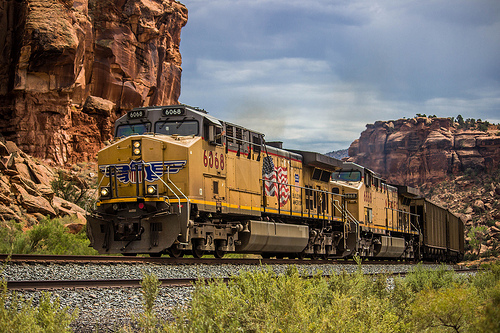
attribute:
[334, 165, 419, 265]
train car — yellow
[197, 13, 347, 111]
clouds — white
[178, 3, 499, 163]
sky — blue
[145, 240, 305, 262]
wheels — small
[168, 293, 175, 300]
rocks — little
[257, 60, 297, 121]
clouds — white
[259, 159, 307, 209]
flag — American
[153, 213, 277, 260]
wheels — steel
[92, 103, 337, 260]
train car — yellow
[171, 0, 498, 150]
sky — blue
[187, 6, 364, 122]
clouds — white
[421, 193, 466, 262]
car — brown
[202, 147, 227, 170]
number — red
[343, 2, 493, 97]
clouds — white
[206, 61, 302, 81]
clouds — white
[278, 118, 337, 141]
clouds — white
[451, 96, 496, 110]
clouds — white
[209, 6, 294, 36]
clouds — white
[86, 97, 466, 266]
train — yellow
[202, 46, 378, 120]
clouds — white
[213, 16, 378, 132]
sky — blue